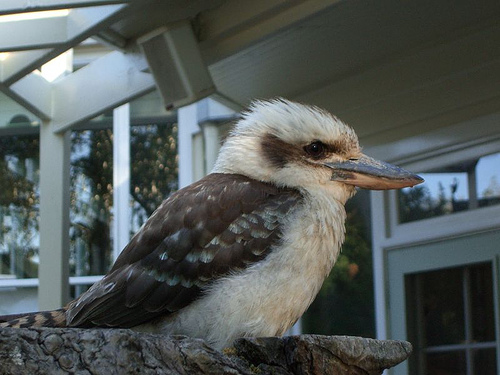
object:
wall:
[206, 0, 499, 168]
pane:
[418, 271, 464, 348]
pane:
[466, 260, 497, 344]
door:
[383, 226, 498, 375]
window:
[395, 150, 499, 375]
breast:
[304, 199, 346, 268]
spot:
[259, 133, 294, 169]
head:
[218, 96, 426, 192]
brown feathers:
[51, 311, 65, 323]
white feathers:
[234, 180, 250, 185]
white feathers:
[184, 206, 191, 213]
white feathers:
[136, 233, 143, 242]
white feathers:
[157, 205, 162, 209]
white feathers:
[104, 282, 115, 292]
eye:
[302, 141, 326, 158]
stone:
[0, 325, 414, 375]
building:
[0, 0, 500, 375]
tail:
[0, 309, 70, 328]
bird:
[0, 96, 426, 352]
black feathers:
[65, 173, 304, 329]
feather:
[0, 98, 357, 354]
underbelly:
[173, 268, 329, 341]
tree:
[127, 121, 180, 241]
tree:
[0, 136, 40, 280]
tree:
[68, 122, 114, 276]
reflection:
[395, 146, 500, 224]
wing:
[70, 172, 306, 332]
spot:
[250, 228, 271, 239]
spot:
[158, 250, 168, 261]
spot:
[198, 251, 213, 263]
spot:
[195, 219, 204, 231]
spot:
[227, 218, 250, 234]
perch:
[0, 325, 414, 374]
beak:
[324, 150, 426, 190]